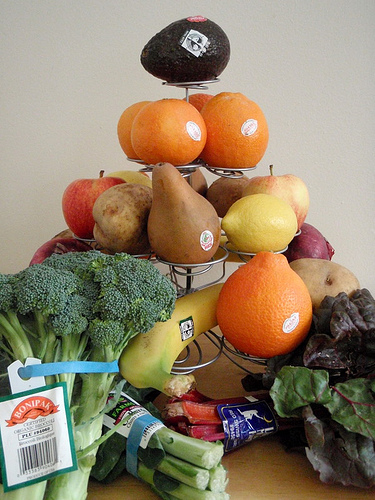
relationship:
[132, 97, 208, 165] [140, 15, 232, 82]
orange and avocado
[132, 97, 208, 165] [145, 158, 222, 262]
orange above pear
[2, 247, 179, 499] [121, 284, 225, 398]
broccoli by banana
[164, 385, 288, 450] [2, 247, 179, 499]
rhubarb by broccoli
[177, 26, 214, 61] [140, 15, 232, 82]
sticker on avocado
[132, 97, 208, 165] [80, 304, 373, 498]
orange on table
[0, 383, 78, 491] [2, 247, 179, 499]
label on broccoli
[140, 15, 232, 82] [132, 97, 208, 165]
avocado and orange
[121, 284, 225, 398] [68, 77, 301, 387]
banana on rack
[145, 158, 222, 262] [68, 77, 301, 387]
pear on rack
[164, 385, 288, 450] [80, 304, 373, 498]
rhubarb on table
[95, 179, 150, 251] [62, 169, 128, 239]
potato with apple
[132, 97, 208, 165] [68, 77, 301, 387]
orange on rack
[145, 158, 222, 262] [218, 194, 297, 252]
pear by lemon